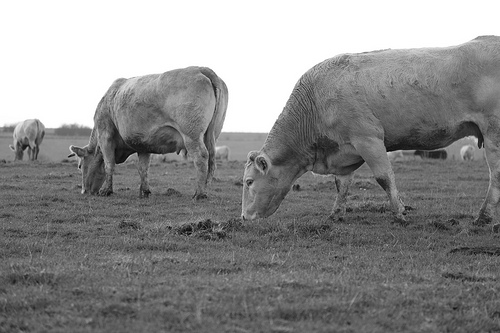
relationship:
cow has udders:
[170, 139, 199, 164] [59, 55, 233, 200]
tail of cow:
[197, 65, 226, 138] [65, 65, 230, 202]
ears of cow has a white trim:
[232, 125, 276, 200] [218, 140, 275, 250]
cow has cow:
[235, 25, 498, 235] [410, 148, 448, 162]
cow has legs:
[239, 139, 306, 228] [333, 155, 400, 229]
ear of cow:
[253, 151, 281, 172] [234, 27, 484, 225]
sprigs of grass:
[47, 231, 82, 268] [100, 246, 179, 294]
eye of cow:
[243, 175, 259, 193] [229, 113, 342, 228]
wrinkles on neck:
[290, 101, 314, 140] [277, 88, 307, 172]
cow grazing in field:
[7, 117, 48, 163] [0, 123, 499, 332]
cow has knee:
[235, 25, 498, 235] [332, 186, 342, 204]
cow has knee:
[235, 25, 498, 235] [375, 173, 394, 193]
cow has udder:
[65, 65, 230, 202] [170, 133, 190, 157]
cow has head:
[65, 65, 230, 202] [66, 143, 106, 196]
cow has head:
[238, 34, 500, 235] [238, 143, 285, 221]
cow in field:
[412, 147, 449, 162] [2, 130, 499, 329]